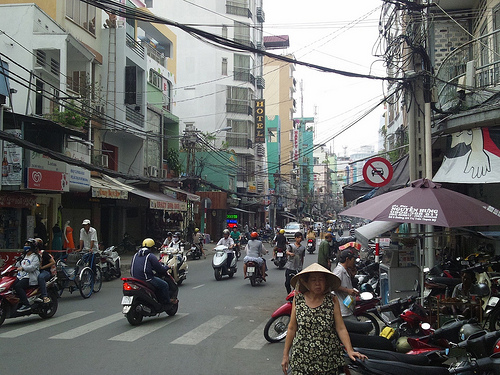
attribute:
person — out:
[280, 262, 369, 373]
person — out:
[332, 248, 360, 315]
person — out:
[283, 231, 305, 301]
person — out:
[316, 231, 334, 267]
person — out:
[129, 236, 178, 306]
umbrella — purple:
[335, 180, 495, 247]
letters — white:
[385, 200, 440, 225]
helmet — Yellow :
[142, 235, 155, 249]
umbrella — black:
[339, 166, 478, 247]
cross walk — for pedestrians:
[55, 306, 237, 352]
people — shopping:
[9, 202, 389, 349]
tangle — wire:
[373, 4, 437, 104]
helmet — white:
[221, 227, 231, 234]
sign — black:
[250, 89, 274, 147]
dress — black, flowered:
[285, 291, 338, 366]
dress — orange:
[60, 217, 114, 277]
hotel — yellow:
[249, 96, 267, 140]